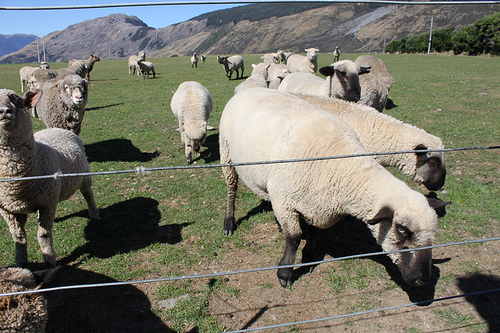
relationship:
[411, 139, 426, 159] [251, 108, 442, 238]
ear attached to sheep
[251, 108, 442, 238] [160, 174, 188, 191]
sheep looking at grass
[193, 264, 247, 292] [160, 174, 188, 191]
patch in grass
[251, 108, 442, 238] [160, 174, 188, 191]
sheep are eating grass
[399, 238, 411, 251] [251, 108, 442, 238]
eye of sheep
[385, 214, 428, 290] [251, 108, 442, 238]
face of sheep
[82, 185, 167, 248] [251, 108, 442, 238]
shadow of sheep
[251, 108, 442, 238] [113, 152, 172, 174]
sheep are behind fence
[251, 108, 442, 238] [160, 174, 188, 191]
sheep are on grass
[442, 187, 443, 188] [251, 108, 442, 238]
nose on sheep